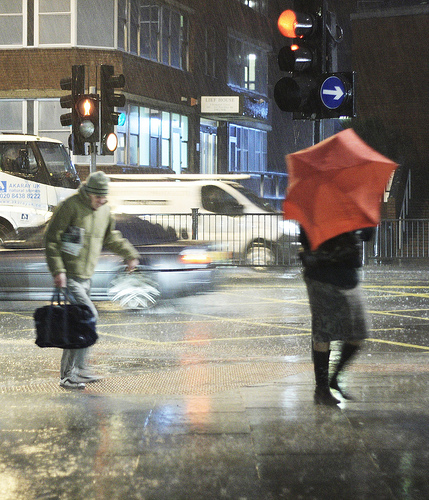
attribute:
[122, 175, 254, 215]
van — white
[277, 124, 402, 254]
umbrella — red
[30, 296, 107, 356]
canvas briefcase — black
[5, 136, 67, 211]
truck — white, large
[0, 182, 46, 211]
words — blue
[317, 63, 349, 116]
directional light — white, blue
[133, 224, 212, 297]
car — black, white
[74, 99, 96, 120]
signal light — red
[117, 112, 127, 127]
signal light — green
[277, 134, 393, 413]
woman — walking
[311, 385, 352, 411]
boots — black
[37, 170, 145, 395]
man — walking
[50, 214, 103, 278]
jacket — green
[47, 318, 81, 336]
bag — blue, black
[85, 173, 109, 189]
cap — black, gray, green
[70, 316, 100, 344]
suitcase — black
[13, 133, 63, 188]
bus — white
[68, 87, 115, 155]
traffic light — bright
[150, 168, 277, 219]
vehicle — white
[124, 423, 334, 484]
road — wet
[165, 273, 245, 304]
light — white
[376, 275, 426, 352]
lines — yellow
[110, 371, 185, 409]
grates — silver